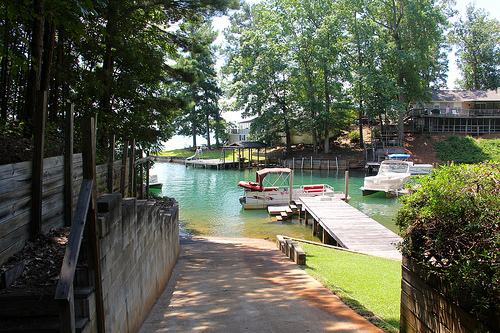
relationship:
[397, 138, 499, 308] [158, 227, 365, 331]
hedge by dirt path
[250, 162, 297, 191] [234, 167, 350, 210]
canopy on boat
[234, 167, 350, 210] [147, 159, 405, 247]
boat on water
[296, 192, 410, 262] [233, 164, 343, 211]
dock by boat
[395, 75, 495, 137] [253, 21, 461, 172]
building by trees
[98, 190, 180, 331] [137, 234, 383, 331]
stone wall next to dirt path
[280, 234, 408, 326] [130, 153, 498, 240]
lawn along river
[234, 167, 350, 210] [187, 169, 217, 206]
boat sitting in water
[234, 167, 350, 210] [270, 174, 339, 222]
boat by dock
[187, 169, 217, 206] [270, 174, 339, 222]
water by dock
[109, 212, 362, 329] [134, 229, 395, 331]
shadows on ground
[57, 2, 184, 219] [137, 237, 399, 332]
tree creating shadows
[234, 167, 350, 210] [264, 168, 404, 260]
boat at dock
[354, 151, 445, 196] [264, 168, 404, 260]
boat at dock